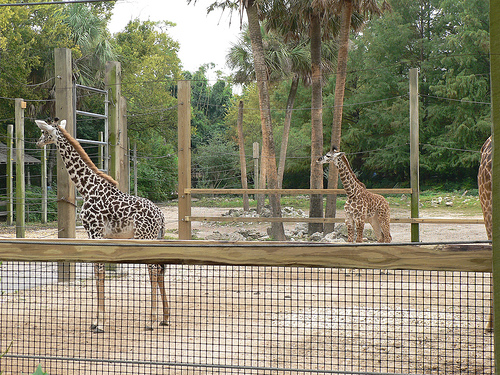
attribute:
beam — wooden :
[180, 185, 413, 195]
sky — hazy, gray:
[111, 0, 244, 37]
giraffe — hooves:
[34, 118, 169, 333]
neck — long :
[330, 161, 364, 201]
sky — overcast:
[138, 6, 260, 91]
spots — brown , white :
[84, 193, 138, 235]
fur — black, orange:
[56, 125, 119, 194]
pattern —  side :
[100, 200, 128, 215]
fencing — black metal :
[234, 266, 415, 358]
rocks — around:
[182, 194, 319, 269]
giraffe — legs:
[288, 108, 410, 286]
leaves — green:
[10, 1, 485, 194]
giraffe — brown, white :
[18, 106, 191, 328]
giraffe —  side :
[96, 189, 163, 221]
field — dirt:
[7, 193, 482, 371]